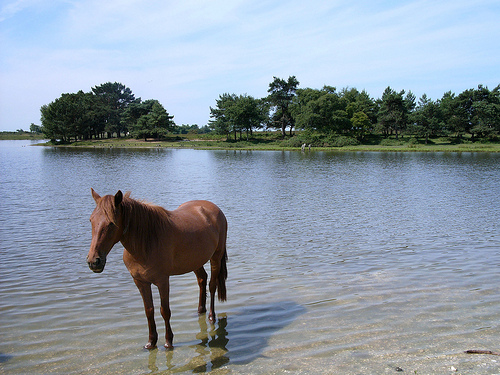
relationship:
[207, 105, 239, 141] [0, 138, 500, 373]
tree beside water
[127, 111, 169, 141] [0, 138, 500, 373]
tree beside water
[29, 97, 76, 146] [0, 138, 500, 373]
tree beside water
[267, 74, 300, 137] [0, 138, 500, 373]
tree beside water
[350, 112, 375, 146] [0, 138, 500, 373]
tree beside water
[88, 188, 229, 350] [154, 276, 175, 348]
horse has leg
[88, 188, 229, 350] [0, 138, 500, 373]
horse in water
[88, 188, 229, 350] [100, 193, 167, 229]
horse has mane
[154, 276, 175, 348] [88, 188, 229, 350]
leg of horse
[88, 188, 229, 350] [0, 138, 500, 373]
horse standing in water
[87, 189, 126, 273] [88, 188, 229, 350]
head of horse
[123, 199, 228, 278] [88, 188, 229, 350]
body of horse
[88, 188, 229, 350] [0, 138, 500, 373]
horse wading in water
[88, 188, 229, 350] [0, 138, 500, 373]
horse standing in lake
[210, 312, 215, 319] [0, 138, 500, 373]
hoof in water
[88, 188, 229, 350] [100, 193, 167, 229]
horse with mane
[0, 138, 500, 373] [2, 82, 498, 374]
water in area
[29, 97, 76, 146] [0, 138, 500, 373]
tree near water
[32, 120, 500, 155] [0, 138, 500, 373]
land near water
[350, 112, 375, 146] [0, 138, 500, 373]
tree near water